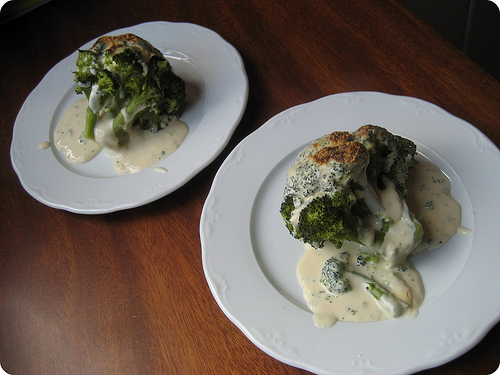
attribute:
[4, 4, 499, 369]
tabletop — brown wood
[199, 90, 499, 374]
plate — white, round